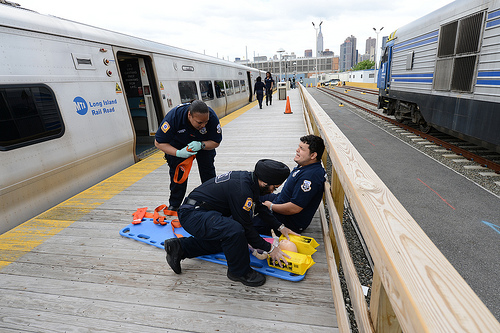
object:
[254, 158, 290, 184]
turban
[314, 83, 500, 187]
track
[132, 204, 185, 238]
straps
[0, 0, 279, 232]
train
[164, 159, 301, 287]
emergency worker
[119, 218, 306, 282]
backboard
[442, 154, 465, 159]
tie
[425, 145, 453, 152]
cross tie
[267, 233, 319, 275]
head supports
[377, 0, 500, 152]
train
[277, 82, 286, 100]
trashcan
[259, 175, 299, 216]
tie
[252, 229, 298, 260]
doll baby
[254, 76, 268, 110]
lady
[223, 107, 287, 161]
platform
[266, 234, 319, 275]
baby doll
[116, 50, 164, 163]
door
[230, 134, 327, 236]
hurt man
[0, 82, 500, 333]
ground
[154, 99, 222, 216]
person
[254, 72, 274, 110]
person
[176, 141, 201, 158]
blue gloves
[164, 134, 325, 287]
man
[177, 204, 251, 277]
pants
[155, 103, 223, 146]
uniform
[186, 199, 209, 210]
belt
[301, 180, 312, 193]
patch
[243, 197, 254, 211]
patch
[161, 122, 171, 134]
patch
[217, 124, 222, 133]
patch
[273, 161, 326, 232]
shirt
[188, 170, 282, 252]
shirt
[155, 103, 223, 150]
shirt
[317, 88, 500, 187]
tie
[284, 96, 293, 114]
cone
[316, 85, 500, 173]
rail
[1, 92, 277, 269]
line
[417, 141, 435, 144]
tie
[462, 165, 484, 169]
tie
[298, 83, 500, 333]
railing